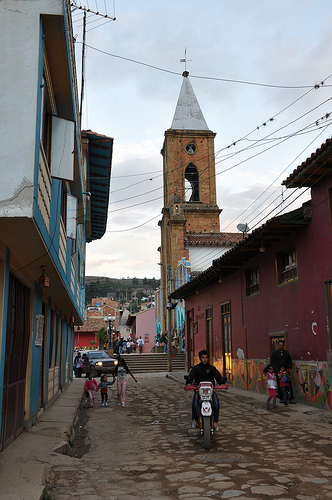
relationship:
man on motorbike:
[188, 345, 222, 379] [183, 380, 229, 451]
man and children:
[262, 336, 294, 363] [259, 357, 298, 411]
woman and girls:
[108, 353, 134, 384] [84, 369, 98, 406]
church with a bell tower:
[145, 30, 247, 292] [162, 134, 221, 212]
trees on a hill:
[98, 275, 140, 303] [91, 274, 146, 310]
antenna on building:
[71, 0, 114, 99] [6, 1, 148, 382]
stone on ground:
[208, 478, 235, 487] [175, 461, 267, 497]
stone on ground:
[178, 458, 215, 471] [169, 453, 257, 497]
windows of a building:
[265, 239, 295, 278] [253, 206, 329, 353]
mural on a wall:
[291, 361, 322, 400] [246, 267, 324, 443]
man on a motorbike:
[186, 345, 228, 433] [185, 377, 236, 450]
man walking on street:
[270, 338, 297, 405] [55, 354, 329, 497]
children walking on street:
[262, 363, 280, 410] [23, 356, 327, 494]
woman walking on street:
[112, 356, 137, 407] [21, 368, 330, 495]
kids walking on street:
[96, 372, 116, 404] [60, 367, 331, 495]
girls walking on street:
[84, 369, 98, 406] [21, 368, 330, 495]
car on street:
[77, 343, 116, 372] [30, 342, 320, 497]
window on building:
[222, 329, 229, 340] [181, 136, 330, 370]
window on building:
[221, 316, 231, 354] [177, 175, 323, 402]